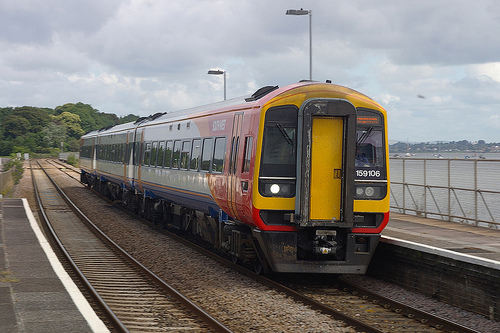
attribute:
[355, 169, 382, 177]
numbers — white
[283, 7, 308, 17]
light — off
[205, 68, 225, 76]
light — off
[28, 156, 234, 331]
track — empty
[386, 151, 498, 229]
water — calm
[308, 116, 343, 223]
door — yellow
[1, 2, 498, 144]
clouds — gray, large, white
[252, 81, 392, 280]
train front — yellow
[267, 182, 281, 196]
light — white, circlular, illuminated, round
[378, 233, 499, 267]
line — white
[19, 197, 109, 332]
line — white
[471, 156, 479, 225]
pole — metal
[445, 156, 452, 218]
pole — metal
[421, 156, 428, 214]
pole — metal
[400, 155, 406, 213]
pole — metal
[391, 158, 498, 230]
fence — chain link, silver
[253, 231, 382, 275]
plate — black, metal